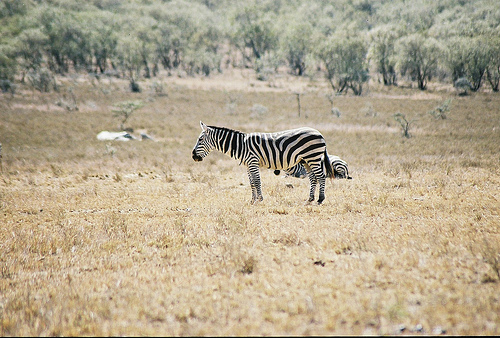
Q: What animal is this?
A: Zebra.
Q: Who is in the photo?
A: Nobody.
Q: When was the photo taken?
A: Daytime.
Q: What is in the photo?
A: Animals.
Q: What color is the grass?
A: Brown.